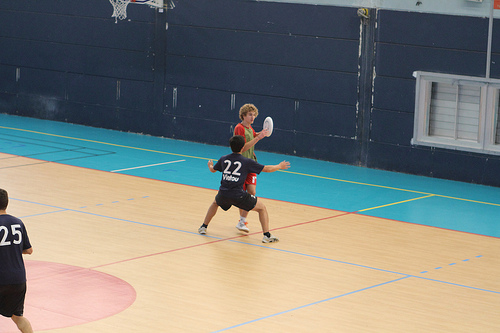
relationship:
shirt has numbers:
[1, 213, 31, 286] [1, 224, 23, 249]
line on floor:
[351, 179, 498, 213] [0, 111, 498, 333]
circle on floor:
[1, 258, 140, 333] [0, 111, 498, 333]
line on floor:
[418, 250, 487, 275] [0, 111, 498, 333]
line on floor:
[420, 275, 500, 299] [0, 111, 498, 333]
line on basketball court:
[94, 238, 226, 272] [0, 111, 498, 333]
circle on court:
[1, 258, 140, 333] [0, 111, 498, 333]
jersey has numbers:
[213, 152, 264, 215] [223, 160, 241, 176]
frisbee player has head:
[227, 103, 271, 234] [236, 101, 260, 125]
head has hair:
[236, 101, 260, 125] [241, 103, 260, 110]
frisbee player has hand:
[227, 103, 271, 234] [258, 130, 273, 140]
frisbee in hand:
[260, 115, 278, 137] [258, 130, 273, 140]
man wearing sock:
[197, 133, 290, 246] [263, 233, 272, 238]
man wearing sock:
[197, 133, 290, 246] [201, 223, 209, 228]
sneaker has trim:
[261, 234, 282, 246] [272, 238, 277, 241]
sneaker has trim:
[200, 224, 210, 234] [272, 238, 277, 241]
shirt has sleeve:
[233, 122, 261, 159] [236, 127, 244, 136]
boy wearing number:
[1, 184, 31, 331] [1, 224, 23, 249]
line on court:
[94, 238, 226, 272] [0, 111, 498, 333]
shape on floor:
[1, 258, 140, 333] [0, 111, 498, 333]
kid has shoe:
[197, 133, 290, 246] [261, 234, 282, 246]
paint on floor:
[329, 185, 345, 192] [0, 111, 498, 333]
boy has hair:
[227, 103, 277, 238] [241, 103, 260, 110]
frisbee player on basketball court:
[227, 103, 271, 234] [0, 111, 498, 333]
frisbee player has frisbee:
[227, 103, 271, 234] [260, 115, 278, 137]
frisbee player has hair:
[227, 103, 271, 234] [241, 103, 260, 110]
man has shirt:
[197, 133, 290, 246] [213, 152, 264, 215]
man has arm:
[197, 133, 290, 246] [249, 159, 295, 175]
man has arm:
[197, 133, 290, 246] [208, 156, 220, 180]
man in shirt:
[197, 133, 290, 246] [213, 152, 264, 215]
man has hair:
[197, 133, 290, 246] [229, 140, 242, 148]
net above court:
[109, 1, 130, 21] [0, 111, 498, 333]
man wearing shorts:
[197, 133, 290, 246] [212, 188, 262, 213]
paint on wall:
[224, 42, 237, 53] [3, 2, 500, 184]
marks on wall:
[357, 19, 363, 124] [3, 2, 500, 184]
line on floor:
[94, 238, 226, 272] [0, 111, 498, 333]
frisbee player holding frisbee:
[227, 103, 271, 234] [262, 116, 273, 137]